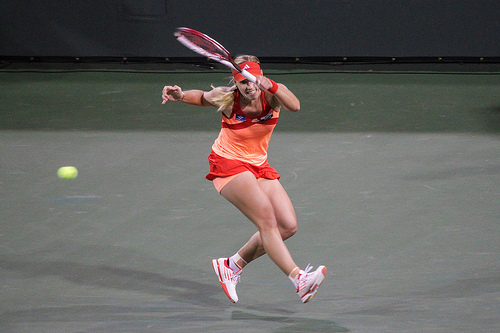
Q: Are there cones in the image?
A: No, there are no cones.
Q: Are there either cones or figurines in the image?
A: No, there are no cones or figurines.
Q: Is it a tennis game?
A: Yes, this is a tennis game.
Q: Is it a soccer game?
A: No, this is a tennis game.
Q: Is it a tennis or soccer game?
A: This is a tennis game.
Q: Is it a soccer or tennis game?
A: This is a tennis game.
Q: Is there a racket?
A: Yes, there is a racket.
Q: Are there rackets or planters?
A: Yes, there is a racket.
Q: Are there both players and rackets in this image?
A: Yes, there are both a racket and a player.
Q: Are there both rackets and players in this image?
A: Yes, there are both a racket and a player.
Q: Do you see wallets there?
A: No, there are no wallets.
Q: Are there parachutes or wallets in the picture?
A: No, there are no wallets or parachutes.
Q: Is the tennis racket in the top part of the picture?
A: Yes, the tennis racket is in the top of the image.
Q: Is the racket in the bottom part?
A: No, the racket is in the top of the image.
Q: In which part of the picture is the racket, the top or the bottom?
A: The racket is in the top of the image.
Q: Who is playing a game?
A: The player is playing a game.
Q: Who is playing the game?
A: The player is playing a game.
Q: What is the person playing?
A: The player is playing a game.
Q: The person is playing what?
A: The player is playing a game.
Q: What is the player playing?
A: The player is playing a game.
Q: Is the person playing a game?
A: Yes, the player is playing a game.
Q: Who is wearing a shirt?
A: The player is wearing a shirt.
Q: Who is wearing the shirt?
A: The player is wearing a shirt.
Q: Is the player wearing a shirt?
A: Yes, the player is wearing a shirt.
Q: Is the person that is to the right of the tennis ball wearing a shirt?
A: Yes, the player is wearing a shirt.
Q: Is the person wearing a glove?
A: No, the player is wearing a shirt.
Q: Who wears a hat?
A: The player wears a hat.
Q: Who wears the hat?
A: The player wears a hat.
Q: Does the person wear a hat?
A: Yes, the player wears a hat.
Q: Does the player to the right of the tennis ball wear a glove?
A: No, the player wears a hat.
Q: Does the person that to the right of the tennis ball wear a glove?
A: No, the player wears a hat.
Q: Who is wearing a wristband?
A: The player is wearing a wristband.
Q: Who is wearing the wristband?
A: The player is wearing a wristband.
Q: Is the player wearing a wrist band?
A: Yes, the player is wearing a wrist band.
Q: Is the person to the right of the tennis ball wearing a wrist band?
A: Yes, the player is wearing a wrist band.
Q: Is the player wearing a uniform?
A: No, the player is wearing a wrist band.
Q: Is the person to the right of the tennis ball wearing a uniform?
A: No, the player is wearing a wrist band.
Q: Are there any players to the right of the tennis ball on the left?
A: Yes, there is a player to the right of the tennis ball.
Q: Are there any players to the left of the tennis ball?
A: No, the player is to the right of the tennis ball.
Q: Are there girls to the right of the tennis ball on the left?
A: No, there is a player to the right of the tennis ball.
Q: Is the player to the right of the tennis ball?
A: Yes, the player is to the right of the tennis ball.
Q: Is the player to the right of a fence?
A: No, the player is to the right of the tennis ball.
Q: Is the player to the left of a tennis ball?
A: No, the player is to the right of a tennis ball.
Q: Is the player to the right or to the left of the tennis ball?
A: The player is to the right of the tennis ball.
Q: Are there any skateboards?
A: No, there are no skateboards.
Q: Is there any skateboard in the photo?
A: No, there are no skateboards.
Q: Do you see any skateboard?
A: No, there are no skateboards.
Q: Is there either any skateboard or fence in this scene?
A: No, there are no skateboards or fences.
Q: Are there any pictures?
A: No, there are no pictures.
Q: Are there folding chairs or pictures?
A: No, there are no pictures or folding chairs.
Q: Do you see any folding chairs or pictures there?
A: No, there are no pictures or folding chairs.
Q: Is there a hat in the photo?
A: Yes, there is a hat.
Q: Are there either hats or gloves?
A: Yes, there is a hat.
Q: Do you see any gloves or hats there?
A: Yes, there is a hat.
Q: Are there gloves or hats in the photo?
A: Yes, there is a hat.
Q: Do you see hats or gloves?
A: Yes, there is a hat.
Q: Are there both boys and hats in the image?
A: No, there is a hat but no boys.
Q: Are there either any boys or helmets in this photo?
A: No, there are no boys or helmets.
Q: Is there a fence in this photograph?
A: No, there are no fences.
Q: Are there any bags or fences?
A: No, there are no fences or bags.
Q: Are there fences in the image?
A: No, there are no fences.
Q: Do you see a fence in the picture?
A: No, there are no fences.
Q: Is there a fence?
A: No, there are no fences.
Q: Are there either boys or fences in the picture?
A: No, there are no fences or boys.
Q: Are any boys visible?
A: No, there are no boys.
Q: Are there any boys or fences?
A: No, there are no boys or fences.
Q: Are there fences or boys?
A: No, there are no boys or fences.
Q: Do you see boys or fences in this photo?
A: No, there are no boys or fences.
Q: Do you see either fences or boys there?
A: No, there are no boys or fences.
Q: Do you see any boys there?
A: No, there are no boys.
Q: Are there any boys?
A: No, there are no boys.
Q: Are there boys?
A: No, there are no boys.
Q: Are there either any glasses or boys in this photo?
A: No, there are no boys or glasses.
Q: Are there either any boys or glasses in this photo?
A: No, there are no boys or glasses.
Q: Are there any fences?
A: No, there are no fences.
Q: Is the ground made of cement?
A: Yes, the ground is made of cement.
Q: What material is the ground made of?
A: The ground is made of cement.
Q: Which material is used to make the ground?
A: The ground is made of cement.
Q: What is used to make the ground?
A: The ground is made of cement.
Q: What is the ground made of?
A: The ground is made of concrete.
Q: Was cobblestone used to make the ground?
A: No, the ground is made of concrete.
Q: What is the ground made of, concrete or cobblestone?
A: The ground is made of concrete.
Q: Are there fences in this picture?
A: No, there are no fences.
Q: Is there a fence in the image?
A: No, there are no fences.